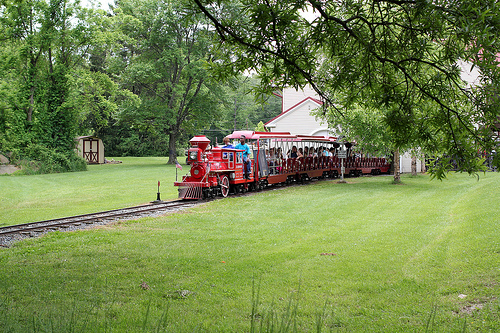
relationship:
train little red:
[165, 115, 256, 190] [212, 165, 225, 168]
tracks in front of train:
[148, 197, 175, 219] [165, 115, 256, 190]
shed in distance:
[71, 129, 113, 167] [105, 71, 151, 102]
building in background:
[269, 71, 373, 136] [242, 76, 284, 122]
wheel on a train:
[220, 176, 230, 195] [165, 115, 256, 190]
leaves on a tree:
[464, 12, 488, 35] [384, 4, 483, 75]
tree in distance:
[384, 4, 483, 75] [105, 71, 151, 102]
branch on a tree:
[203, 9, 344, 40] [384, 4, 483, 75]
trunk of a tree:
[164, 138, 177, 163] [159, 62, 189, 158]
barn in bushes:
[68, 127, 107, 163] [47, 118, 80, 165]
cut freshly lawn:
[459, 293, 480, 318] [303, 191, 430, 313]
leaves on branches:
[464, 12, 488, 35] [343, 13, 408, 46]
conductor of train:
[238, 133, 253, 175] [165, 115, 256, 190]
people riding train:
[255, 139, 327, 162] [165, 115, 256, 190]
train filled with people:
[165, 115, 256, 190] [255, 139, 327, 162]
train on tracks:
[165, 115, 256, 190] [148, 197, 175, 219]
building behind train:
[269, 71, 373, 136] [165, 115, 256, 190]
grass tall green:
[287, 203, 315, 220] [387, 198, 416, 214]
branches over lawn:
[343, 13, 408, 46] [303, 191, 430, 313]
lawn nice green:
[303, 191, 430, 313] [387, 198, 416, 214]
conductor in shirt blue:
[235, 133, 254, 175] [241, 147, 248, 149]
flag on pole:
[175, 162, 184, 168] [175, 163, 179, 182]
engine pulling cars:
[185, 133, 240, 202] [248, 132, 395, 173]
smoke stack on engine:
[190, 136, 209, 144] [185, 133, 240, 202]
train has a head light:
[165, 115, 256, 190] [187, 150, 199, 159]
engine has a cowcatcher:
[185, 133, 240, 202] [178, 185, 206, 199]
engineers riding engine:
[214, 133, 255, 178] [185, 133, 240, 202]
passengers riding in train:
[266, 145, 378, 165] [165, 115, 256, 190]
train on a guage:
[165, 115, 256, 190] [141, 202, 179, 210]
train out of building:
[165, 115, 256, 190] [269, 71, 373, 136]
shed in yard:
[71, 129, 113, 167] [68, 154, 153, 195]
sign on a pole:
[334, 141, 347, 158] [341, 159, 347, 176]